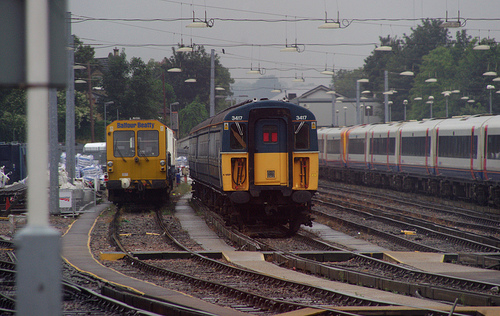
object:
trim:
[221, 152, 251, 192]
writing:
[116, 122, 158, 128]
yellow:
[141, 163, 154, 174]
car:
[103, 119, 176, 212]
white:
[442, 119, 458, 127]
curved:
[105, 207, 472, 316]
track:
[109, 204, 467, 316]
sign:
[0, 0, 80, 87]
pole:
[14, 0, 64, 316]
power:
[70, 13, 500, 29]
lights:
[184, 21, 207, 28]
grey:
[20, 239, 40, 251]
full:
[2, 35, 235, 144]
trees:
[328, 18, 500, 120]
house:
[270, 84, 350, 99]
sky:
[59, 2, 500, 104]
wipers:
[113, 144, 131, 164]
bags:
[75, 152, 95, 166]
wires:
[61, 14, 500, 26]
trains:
[175, 97, 320, 232]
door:
[253, 118, 288, 189]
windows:
[137, 130, 160, 142]